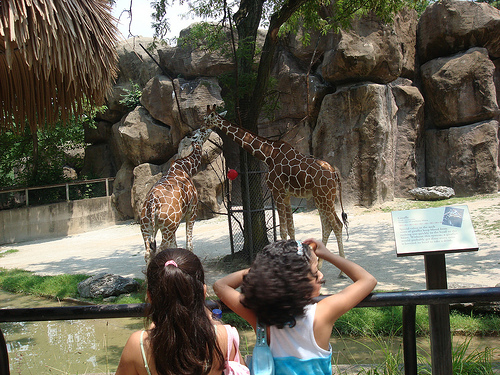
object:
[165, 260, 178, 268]
hair tie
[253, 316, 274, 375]
purse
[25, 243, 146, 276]
shadow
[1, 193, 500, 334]
ground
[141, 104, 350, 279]
giraffe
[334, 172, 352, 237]
tail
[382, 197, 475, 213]
grass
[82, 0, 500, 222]
rocks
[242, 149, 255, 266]
pole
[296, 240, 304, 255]
headband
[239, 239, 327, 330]
hair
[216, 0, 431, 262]
tree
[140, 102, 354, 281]
giraffes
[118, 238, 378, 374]
girl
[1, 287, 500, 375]
fence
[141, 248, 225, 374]
hair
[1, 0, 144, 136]
palm fonds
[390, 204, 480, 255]
sign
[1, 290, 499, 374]
water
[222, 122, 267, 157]
neck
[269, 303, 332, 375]
dress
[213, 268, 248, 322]
arm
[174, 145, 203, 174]
neck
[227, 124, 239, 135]
spot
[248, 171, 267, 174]
bar